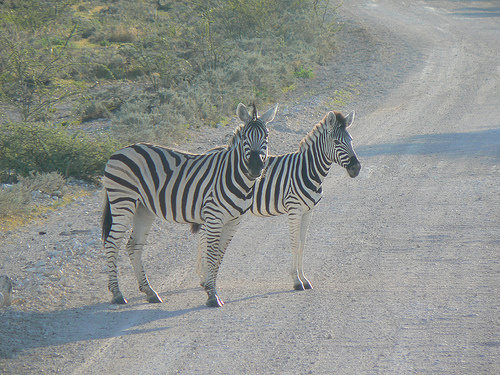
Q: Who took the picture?
A: A tourist.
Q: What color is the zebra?
A: Black and white.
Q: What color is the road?
A: Grey.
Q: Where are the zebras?
A: On the road.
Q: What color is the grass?
A: Grey.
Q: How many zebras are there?
A: Two.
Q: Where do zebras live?
A: Africa.